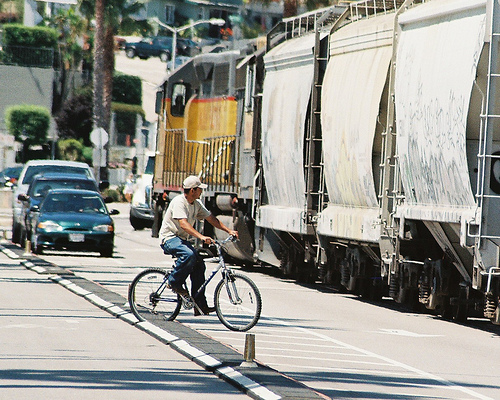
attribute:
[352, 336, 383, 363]
mark — white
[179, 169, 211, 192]
cap — white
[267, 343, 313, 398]
shadow — cast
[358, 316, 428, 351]
arrow — white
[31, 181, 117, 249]
car — green, white, parked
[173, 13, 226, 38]
lamp — white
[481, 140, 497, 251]
ladder — metal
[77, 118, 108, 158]
sign — black, back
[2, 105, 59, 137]
bush — square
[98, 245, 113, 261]
wheel — black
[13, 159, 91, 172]
car — white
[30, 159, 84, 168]
truck — parked